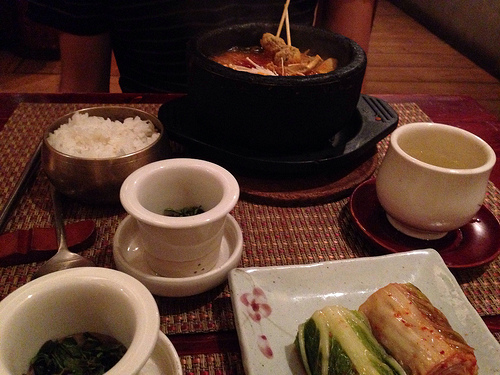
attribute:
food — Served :
[290, 278, 481, 373]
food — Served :
[25, 325, 129, 373]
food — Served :
[42, 105, 163, 157]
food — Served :
[161, 200, 207, 215]